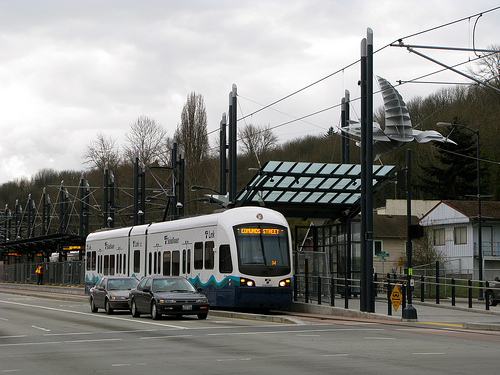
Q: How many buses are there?
A: One.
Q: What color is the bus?
A: Blue and white.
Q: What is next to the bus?
A: Two cars.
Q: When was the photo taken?
A: During the day.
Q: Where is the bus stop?
A: On the sidewalk.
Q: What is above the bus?
A: Wires.